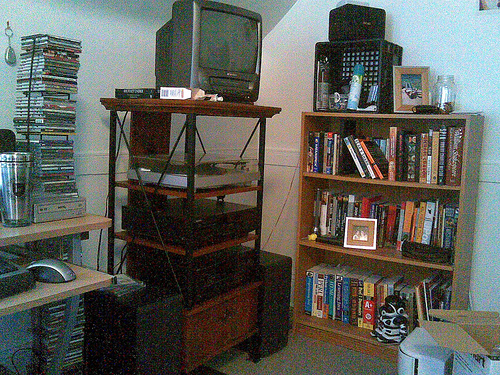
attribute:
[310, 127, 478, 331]
books — plenty, full, stack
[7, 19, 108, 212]
cds — stack, tall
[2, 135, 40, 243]
cup — black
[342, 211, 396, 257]
picture — man, frame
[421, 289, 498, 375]
box — white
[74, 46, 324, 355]
center — entertainment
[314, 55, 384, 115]
freshener — air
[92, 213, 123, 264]
cord — electrical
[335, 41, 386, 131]
can — blue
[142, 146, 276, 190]
player — silver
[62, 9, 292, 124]
television — gray